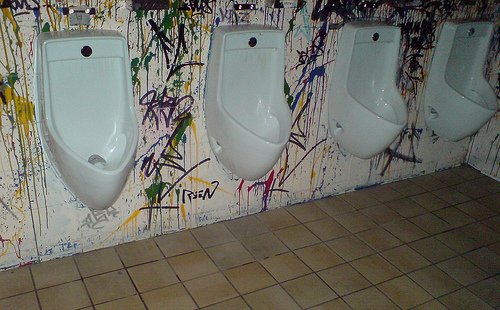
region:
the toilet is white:
[35, 39, 197, 270]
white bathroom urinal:
[37, 26, 153, 213]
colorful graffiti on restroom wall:
[119, 8, 266, 227]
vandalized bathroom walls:
[21, 7, 451, 208]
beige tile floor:
[277, 220, 458, 291]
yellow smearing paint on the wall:
[8, 94, 63, 246]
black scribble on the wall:
[143, 78, 218, 217]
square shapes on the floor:
[292, 214, 456, 296]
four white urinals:
[30, 5, 497, 214]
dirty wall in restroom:
[134, 3, 316, 219]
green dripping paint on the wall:
[137, 7, 213, 219]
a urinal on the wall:
[32, 25, 143, 216]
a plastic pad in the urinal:
[83, 147, 113, 167]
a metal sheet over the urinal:
[59, 0, 97, 29]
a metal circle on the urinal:
[78, 44, 95, 59]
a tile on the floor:
[179, 270, 242, 309]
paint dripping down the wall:
[1, 122, 54, 264]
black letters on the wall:
[178, 175, 221, 210]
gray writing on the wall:
[75, 199, 122, 236]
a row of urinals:
[26, 15, 498, 216]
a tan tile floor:
[2, 160, 498, 309]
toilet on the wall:
[43, 41, 168, 210]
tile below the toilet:
[227, 226, 322, 293]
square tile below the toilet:
[258, 249, 338, 300]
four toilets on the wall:
[40, 20, 487, 242]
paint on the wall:
[152, 48, 193, 123]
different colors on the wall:
[150, 59, 199, 147]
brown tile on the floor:
[281, 227, 362, 281]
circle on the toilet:
[72, 33, 112, 69]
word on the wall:
[166, 177, 228, 228]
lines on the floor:
[280, 243, 360, 294]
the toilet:
[14, 28, 211, 306]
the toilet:
[24, 25, 150, 220]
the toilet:
[32, 57, 120, 177]